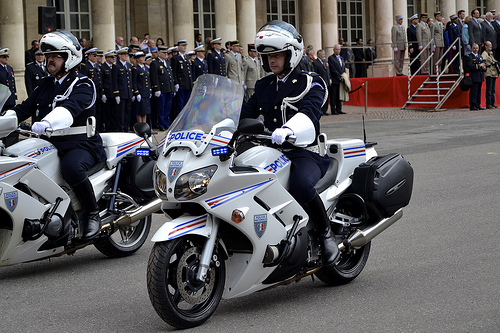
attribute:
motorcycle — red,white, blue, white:
[147, 72, 415, 327]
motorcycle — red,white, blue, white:
[0, 82, 162, 268]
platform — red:
[328, 75, 499, 108]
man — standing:
[328, 43, 352, 116]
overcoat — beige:
[339, 67, 350, 102]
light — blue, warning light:
[212, 145, 229, 156]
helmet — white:
[253, 20, 304, 72]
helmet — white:
[38, 28, 84, 73]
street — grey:
[0, 116, 498, 331]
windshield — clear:
[167, 72, 245, 139]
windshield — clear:
[0, 84, 12, 117]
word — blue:
[167, 132, 204, 142]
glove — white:
[29, 120, 47, 134]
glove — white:
[271, 127, 292, 143]